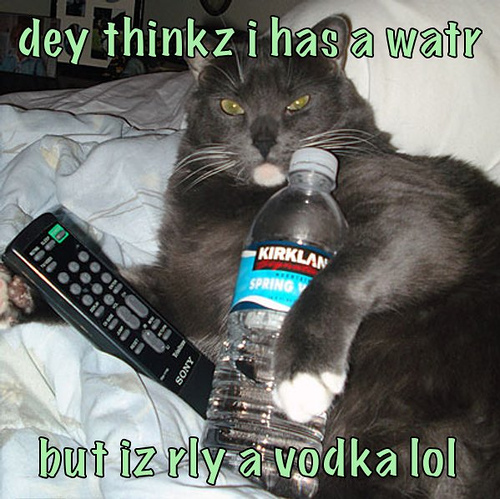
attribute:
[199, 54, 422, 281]
cat — big, white, grey, large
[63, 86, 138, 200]
bed — plastic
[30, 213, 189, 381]
remote — black, sony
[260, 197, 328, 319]
bottle — white